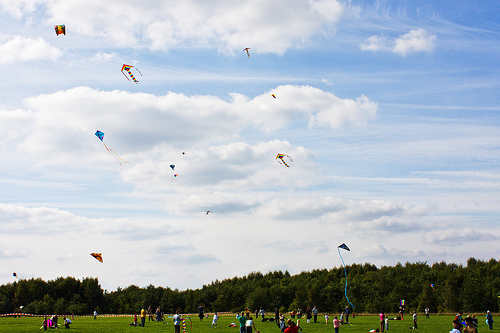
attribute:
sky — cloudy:
[21, 24, 412, 201]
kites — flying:
[303, 218, 385, 303]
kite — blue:
[335, 240, 356, 313]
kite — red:
[88, 250, 106, 264]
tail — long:
[101, 140, 122, 166]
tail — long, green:
[335, 249, 356, 307]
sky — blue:
[317, 2, 483, 177]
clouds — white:
[61, 80, 341, 190]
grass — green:
[75, 318, 121, 331]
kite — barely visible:
[179, 148, 188, 157]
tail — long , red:
[100, 140, 125, 171]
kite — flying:
[239, 41, 251, 59]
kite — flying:
[166, 157, 176, 171]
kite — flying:
[90, 126, 104, 142]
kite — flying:
[48, 19, 68, 37]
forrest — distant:
[8, 255, 498, 325]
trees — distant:
[39, 270, 108, 310]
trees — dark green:
[2, 255, 498, 313]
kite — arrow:
[117, 55, 140, 87]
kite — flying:
[272, 146, 293, 171]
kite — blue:
[90, 126, 108, 142]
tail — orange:
[101, 141, 122, 164]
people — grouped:
[12, 294, 499, 326]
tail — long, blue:
[335, 250, 356, 315]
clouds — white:
[2, 3, 498, 270]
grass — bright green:
[6, 308, 494, 330]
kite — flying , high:
[49, 21, 68, 37]